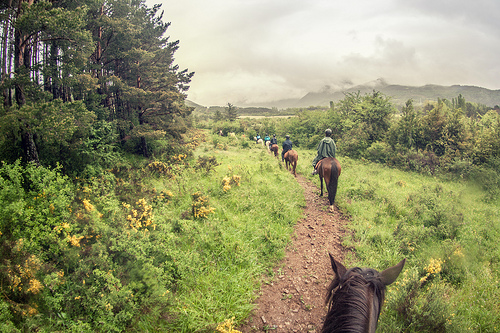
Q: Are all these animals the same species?
A: Yes, all the animals are horses.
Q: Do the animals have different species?
A: No, all the animals are horses.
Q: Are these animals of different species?
A: No, all the animals are horses.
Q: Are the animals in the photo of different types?
A: No, all the animals are horses.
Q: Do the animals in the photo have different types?
A: No, all the animals are horses.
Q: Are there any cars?
A: No, there are no cars.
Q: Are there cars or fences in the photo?
A: No, there are no cars or fences.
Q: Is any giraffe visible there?
A: No, there are no giraffes.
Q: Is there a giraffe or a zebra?
A: No, there are no giraffes or zebras.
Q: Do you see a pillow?
A: No, there are no pillows.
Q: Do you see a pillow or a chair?
A: No, there are no pillows or chairs.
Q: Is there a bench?
A: No, there are no benches.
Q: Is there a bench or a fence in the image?
A: No, there are no benches or fences.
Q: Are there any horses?
A: Yes, there is a horse.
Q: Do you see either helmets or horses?
A: Yes, there is a horse.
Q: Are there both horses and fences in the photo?
A: No, there is a horse but no fences.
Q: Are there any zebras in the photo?
A: No, there are no zebras.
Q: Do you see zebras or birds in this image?
A: No, there are no zebras or birds.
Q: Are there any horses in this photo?
A: Yes, there is a horse.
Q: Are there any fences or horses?
A: Yes, there is a horse.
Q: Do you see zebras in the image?
A: No, there are no zebras.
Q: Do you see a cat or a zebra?
A: No, there are no zebras or cats.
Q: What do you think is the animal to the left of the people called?
A: The animal is a horse.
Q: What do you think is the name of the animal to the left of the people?
A: The animal is a horse.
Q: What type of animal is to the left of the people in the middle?
A: The animal is a horse.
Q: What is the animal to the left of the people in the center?
A: The animal is a horse.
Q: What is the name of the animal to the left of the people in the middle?
A: The animal is a horse.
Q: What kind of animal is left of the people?
A: The animal is a horse.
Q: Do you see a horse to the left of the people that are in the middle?
A: Yes, there is a horse to the left of the people.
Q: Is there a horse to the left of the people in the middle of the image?
A: Yes, there is a horse to the left of the people.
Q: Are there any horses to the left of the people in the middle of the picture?
A: Yes, there is a horse to the left of the people.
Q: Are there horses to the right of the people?
A: No, the horse is to the left of the people.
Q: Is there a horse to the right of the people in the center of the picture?
A: No, the horse is to the left of the people.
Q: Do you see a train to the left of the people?
A: No, there is a horse to the left of the people.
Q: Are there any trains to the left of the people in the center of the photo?
A: No, there is a horse to the left of the people.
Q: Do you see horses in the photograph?
A: Yes, there is a horse.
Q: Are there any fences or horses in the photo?
A: Yes, there is a horse.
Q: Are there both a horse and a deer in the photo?
A: No, there is a horse but no deer.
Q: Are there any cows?
A: No, there are no cows.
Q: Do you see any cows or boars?
A: No, there are no cows or boars.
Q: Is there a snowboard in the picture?
A: No, there are no snowboards.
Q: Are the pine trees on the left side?
A: Yes, the pine trees are on the left of the image.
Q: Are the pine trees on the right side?
A: No, the pine trees are on the left of the image.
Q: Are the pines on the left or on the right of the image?
A: The pines are on the left of the image.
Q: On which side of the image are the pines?
A: The pines are on the left of the image.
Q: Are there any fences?
A: No, there are no fences.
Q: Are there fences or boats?
A: No, there are no fences or boats.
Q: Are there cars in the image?
A: No, there are no cars.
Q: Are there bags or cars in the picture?
A: No, there are no cars or bags.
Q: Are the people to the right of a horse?
A: Yes, the people are to the right of a horse.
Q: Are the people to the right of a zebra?
A: No, the people are to the right of a horse.